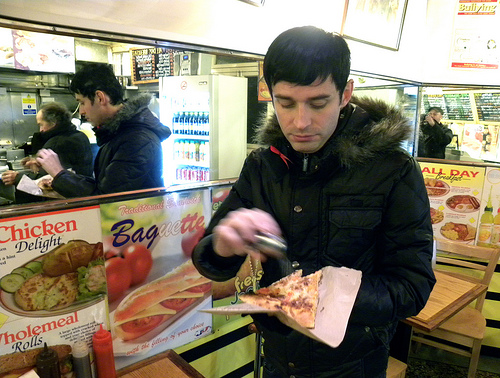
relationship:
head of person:
[261, 22, 354, 154] [193, 20, 443, 375]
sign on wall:
[1, 203, 110, 355] [1, 161, 499, 376]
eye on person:
[272, 99, 295, 106] [255, 24, 415, 353]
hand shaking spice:
[199, 204, 301, 260] [247, 227, 289, 253]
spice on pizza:
[247, 227, 289, 253] [238, 261, 328, 328]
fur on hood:
[333, 90, 404, 177] [336, 86, 399, 174]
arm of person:
[373, 178, 434, 329] [193, 20, 443, 375]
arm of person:
[347, 159, 448, 329] [228, 41, 416, 376]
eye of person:
[272, 99, 295, 106] [193, 20, 443, 375]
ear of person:
[334, 79, 367, 109] [193, 20, 443, 375]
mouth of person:
[286, 129, 323, 142] [193, 20, 443, 375]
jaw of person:
[310, 118, 337, 150] [193, 20, 443, 375]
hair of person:
[262, 19, 344, 85] [193, 20, 443, 375]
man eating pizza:
[37, 66, 167, 192] [238, 267, 322, 327]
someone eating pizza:
[188, 22, 434, 377] [235, 267, 323, 332]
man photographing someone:
[37, 66, 167, 192] [188, 22, 434, 377]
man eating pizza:
[37, 66, 167, 192] [16, 155, 57, 195]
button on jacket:
[289, 201, 303, 218] [190, 87, 440, 375]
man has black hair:
[37, 66, 167, 192] [264, 25, 349, 105]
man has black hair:
[37, 66, 167, 192] [69, 62, 124, 102]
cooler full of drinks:
[155, 72, 247, 191] [170, 98, 220, 190]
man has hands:
[37, 66, 167, 192] [216, 199, 286, 258]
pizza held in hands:
[229, 264, 327, 331] [216, 199, 286, 258]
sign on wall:
[1, 203, 110, 355] [0, 177, 267, 376]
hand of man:
[199, 195, 301, 271] [37, 66, 167, 192]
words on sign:
[0, 216, 83, 256] [0, 215, 122, 355]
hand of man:
[199, 204, 301, 260] [37, 66, 167, 192]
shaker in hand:
[234, 222, 293, 265] [208, 194, 285, 271]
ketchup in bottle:
[92, 347, 114, 376] [91, 323, 113, 374]